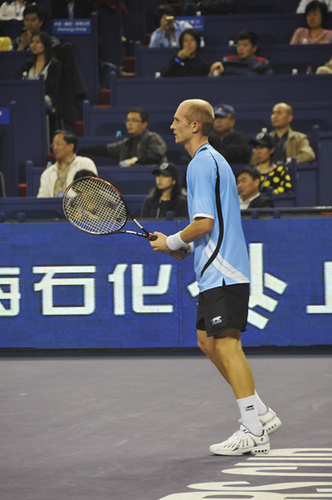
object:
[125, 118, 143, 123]
glasses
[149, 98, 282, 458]
man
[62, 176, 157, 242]
racket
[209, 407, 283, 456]
shoes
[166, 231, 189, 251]
band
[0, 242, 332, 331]
writing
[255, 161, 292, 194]
shirt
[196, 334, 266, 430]
man's leg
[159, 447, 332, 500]
white writing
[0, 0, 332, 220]
man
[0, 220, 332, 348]
blue wall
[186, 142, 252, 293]
jersey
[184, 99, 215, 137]
hair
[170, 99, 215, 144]
bald head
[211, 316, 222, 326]
logo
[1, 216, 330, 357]
stand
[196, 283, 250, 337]
shorts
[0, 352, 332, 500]
court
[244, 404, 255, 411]
logo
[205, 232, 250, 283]
stripes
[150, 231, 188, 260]
hand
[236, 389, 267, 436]
sock